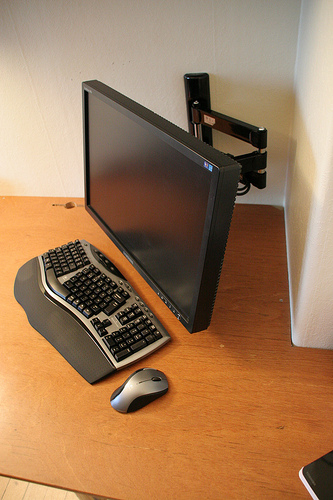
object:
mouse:
[108, 367, 168, 413]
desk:
[0, 193, 333, 500]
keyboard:
[13, 237, 171, 383]